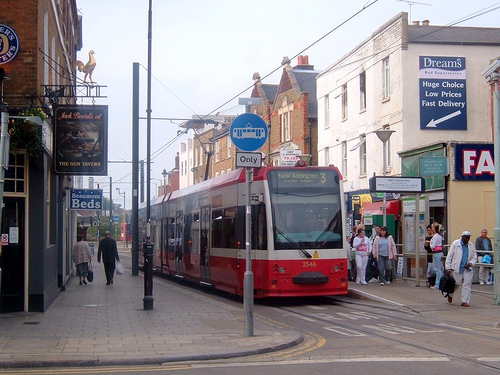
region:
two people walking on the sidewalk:
[71, 228, 123, 283]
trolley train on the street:
[136, 161, 348, 296]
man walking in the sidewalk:
[436, 230, 476, 305]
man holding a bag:
[95, 228, 123, 284]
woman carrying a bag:
[70, 232, 95, 282]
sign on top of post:
[227, 110, 272, 335]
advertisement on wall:
[416, 50, 466, 130]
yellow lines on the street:
[2, 305, 323, 373]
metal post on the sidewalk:
[140, 0, 155, 310]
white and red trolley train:
[137, 164, 351, 303]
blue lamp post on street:
[190, 100, 308, 345]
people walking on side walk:
[353, 215, 412, 296]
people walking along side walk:
[63, 220, 141, 298]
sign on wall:
[406, 45, 483, 153]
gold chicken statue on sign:
[61, 37, 107, 89]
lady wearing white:
[349, 221, 382, 288]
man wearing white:
[436, 225, 497, 319]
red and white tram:
[120, 145, 369, 320]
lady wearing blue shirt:
[369, 222, 407, 289]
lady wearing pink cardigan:
[367, 215, 414, 295]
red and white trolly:
[141, 167, 348, 301]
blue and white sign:
[231, 113, 268, 150]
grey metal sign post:
[243, 168, 253, 336]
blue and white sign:
[71, 189, 103, 211]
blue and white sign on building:
[419, 55, 468, 131]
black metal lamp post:
[144, 0, 152, 308]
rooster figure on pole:
[73, 51, 96, 81]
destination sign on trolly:
[274, 170, 336, 186]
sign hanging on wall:
[55, 105, 107, 175]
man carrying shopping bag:
[98, 230, 123, 285]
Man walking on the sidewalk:
[440, 232, 477, 308]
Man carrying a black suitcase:
[435, 231, 477, 307]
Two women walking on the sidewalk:
[351, 225, 398, 285]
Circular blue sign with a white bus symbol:
[228, 111, 269, 151]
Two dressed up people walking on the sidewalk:
[68, 230, 125, 287]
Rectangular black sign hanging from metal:
[40, 83, 110, 176]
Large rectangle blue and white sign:
[417, 54, 467, 131]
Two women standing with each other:
[422, 220, 444, 288]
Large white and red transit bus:
[131, 163, 349, 302]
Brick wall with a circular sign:
[0, 0, 35, 95]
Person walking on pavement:
[441, 215, 479, 338]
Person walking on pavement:
[426, 219, 452, 289]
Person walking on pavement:
[365, 220, 400, 294]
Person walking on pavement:
[350, 226, 377, 292]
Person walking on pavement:
[97, 227, 139, 319]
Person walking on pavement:
[71, 227, 97, 296]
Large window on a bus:
[268, 167, 348, 262]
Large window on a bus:
[205, 196, 300, 265]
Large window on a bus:
[151, 206, 228, 276]